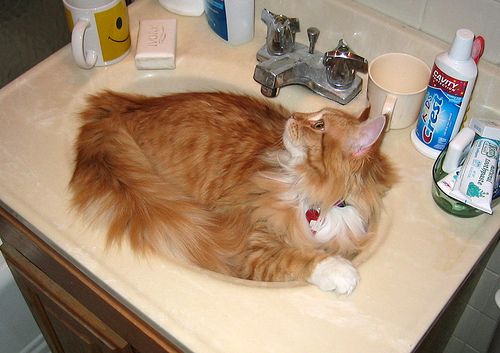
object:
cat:
[68, 78, 394, 287]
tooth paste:
[412, 28, 478, 158]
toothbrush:
[471, 36, 486, 61]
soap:
[133, 18, 177, 72]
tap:
[253, 10, 366, 103]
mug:
[66, 0, 138, 69]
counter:
[381, 222, 461, 300]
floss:
[441, 124, 481, 173]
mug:
[365, 53, 433, 133]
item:
[307, 208, 326, 233]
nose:
[292, 113, 306, 120]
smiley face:
[111, 14, 135, 49]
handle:
[383, 97, 398, 134]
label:
[428, 68, 467, 149]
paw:
[309, 250, 362, 292]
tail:
[76, 146, 212, 257]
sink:
[129, 98, 358, 271]